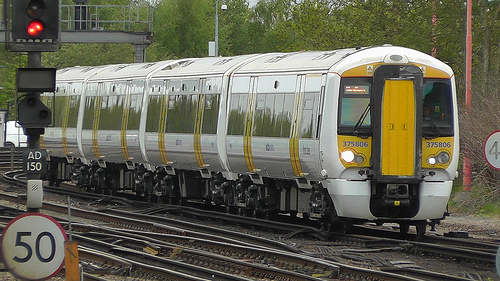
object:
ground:
[2, 130, 499, 277]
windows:
[295, 90, 325, 138]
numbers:
[12, 231, 32, 263]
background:
[2, 2, 499, 205]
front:
[336, 60, 453, 177]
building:
[1, 0, 149, 45]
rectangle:
[380, 73, 421, 177]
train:
[39, 44, 461, 233]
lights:
[341, 151, 355, 163]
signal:
[10, 1, 59, 51]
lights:
[437, 151, 451, 163]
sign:
[0, 212, 67, 280]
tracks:
[83, 192, 287, 279]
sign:
[23, 148, 46, 173]